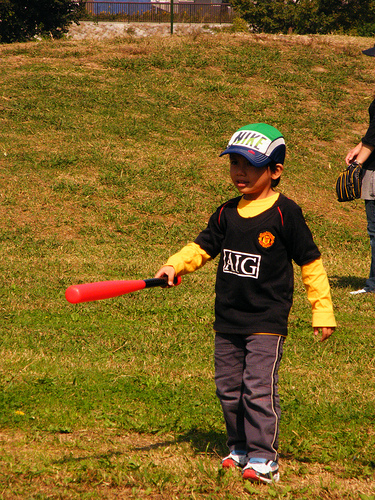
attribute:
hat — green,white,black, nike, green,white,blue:
[217, 117, 290, 169]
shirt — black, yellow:
[156, 194, 346, 330]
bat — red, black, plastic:
[63, 273, 185, 307]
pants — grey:
[206, 320, 288, 460]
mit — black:
[330, 150, 369, 206]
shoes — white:
[215, 443, 289, 485]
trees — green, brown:
[231, 2, 374, 31]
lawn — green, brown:
[1, 35, 373, 498]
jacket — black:
[362, 93, 374, 175]